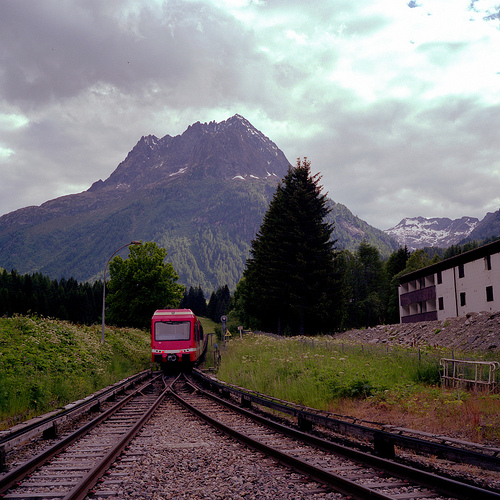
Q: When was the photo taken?
A: Daytime.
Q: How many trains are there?
A: One.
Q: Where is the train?
A: On the tracks.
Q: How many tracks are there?
A: Two.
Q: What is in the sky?
A: Clouds.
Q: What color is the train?
A: Red.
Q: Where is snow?
A: Mountain tops.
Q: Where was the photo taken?
A: Train station.